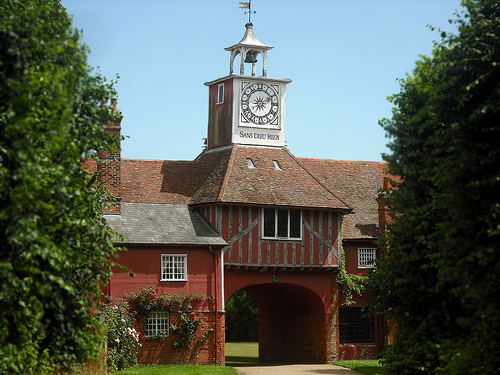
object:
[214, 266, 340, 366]
archway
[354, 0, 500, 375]
hedge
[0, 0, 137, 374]
hedge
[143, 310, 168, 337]
window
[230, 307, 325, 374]
space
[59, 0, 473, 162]
sky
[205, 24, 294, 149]
steeple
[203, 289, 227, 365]
wall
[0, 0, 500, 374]
winter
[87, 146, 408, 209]
roof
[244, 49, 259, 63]
bell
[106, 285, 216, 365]
climbing rose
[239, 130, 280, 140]
words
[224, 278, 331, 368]
tunnel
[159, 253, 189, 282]
window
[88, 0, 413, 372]
church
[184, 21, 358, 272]
tower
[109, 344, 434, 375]
lawn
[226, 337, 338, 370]
pathway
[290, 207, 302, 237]
window part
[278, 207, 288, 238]
window part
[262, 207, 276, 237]
window part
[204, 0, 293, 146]
clock tower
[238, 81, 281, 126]
face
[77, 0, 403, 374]
building